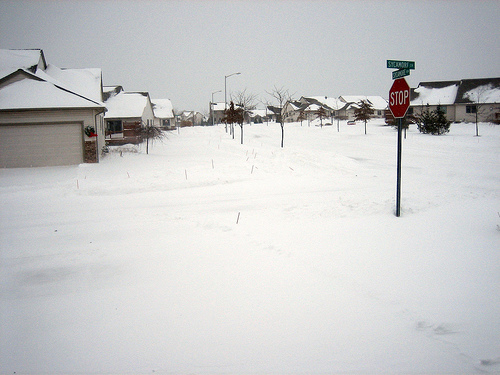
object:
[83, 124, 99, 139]
wreath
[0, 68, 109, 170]
house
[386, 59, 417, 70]
street sign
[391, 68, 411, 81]
street sign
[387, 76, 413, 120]
stop sign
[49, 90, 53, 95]
snow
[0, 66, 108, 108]
roof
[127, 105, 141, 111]
snow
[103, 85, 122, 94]
roof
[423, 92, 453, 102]
snow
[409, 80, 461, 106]
roof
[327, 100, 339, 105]
snow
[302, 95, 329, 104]
roof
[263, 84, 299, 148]
tree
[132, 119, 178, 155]
tree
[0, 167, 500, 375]
yard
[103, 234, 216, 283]
snow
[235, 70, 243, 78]
light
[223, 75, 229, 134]
pole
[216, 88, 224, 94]
light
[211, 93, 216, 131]
pole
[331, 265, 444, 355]
snow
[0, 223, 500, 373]
street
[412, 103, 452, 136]
bush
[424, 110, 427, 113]
leaves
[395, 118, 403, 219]
pole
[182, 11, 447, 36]
sky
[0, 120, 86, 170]
garage door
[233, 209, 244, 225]
stick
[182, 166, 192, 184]
stick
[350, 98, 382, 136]
tree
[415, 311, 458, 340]
footprint